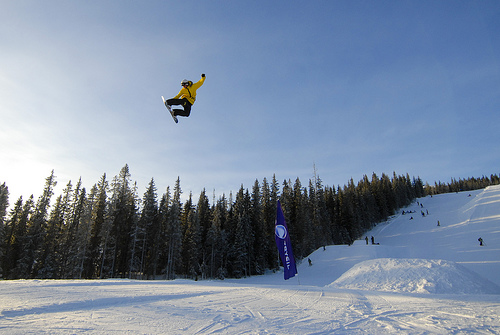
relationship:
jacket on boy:
[169, 74, 208, 104] [164, 74, 208, 118]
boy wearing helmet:
[164, 74, 208, 118] [181, 77, 193, 87]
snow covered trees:
[3, 185, 495, 334] [0, 162, 499, 279]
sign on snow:
[268, 194, 303, 281] [311, 200, 496, 331]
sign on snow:
[268, 194, 303, 281] [8, 269, 403, 334]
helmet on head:
[178, 77, 192, 85] [179, 76, 194, 88]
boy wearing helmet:
[165, 69, 208, 118] [149, 73, 203, 87]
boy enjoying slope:
[164, 74, 208, 118] [288, 160, 498, 304]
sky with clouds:
[0, 0, 498, 221] [0, 0, 340, 216]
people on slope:
[357, 197, 491, 255] [280, 187, 480, 297]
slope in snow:
[466, 173, 496, 304] [305, 211, 498, 331]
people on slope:
[476, 235, 484, 247] [364, 182, 497, 309]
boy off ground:
[164, 74, 208, 118] [0, 270, 499, 334]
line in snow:
[246, 305, 255, 320] [3, 185, 495, 334]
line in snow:
[435, 309, 474, 319] [3, 185, 495, 334]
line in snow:
[343, 310, 388, 323] [3, 185, 495, 334]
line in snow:
[196, 326, 229, 333] [3, 185, 495, 334]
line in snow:
[439, 307, 474, 321] [3, 185, 495, 334]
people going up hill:
[476, 235, 484, 247] [264, 180, 477, 292]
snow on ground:
[255, 253, 346, 325] [0, 270, 480, 329]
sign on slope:
[274, 223, 288, 240] [318, 227, 455, 302]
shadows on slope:
[1, 192, 499, 332] [280, 187, 480, 297]